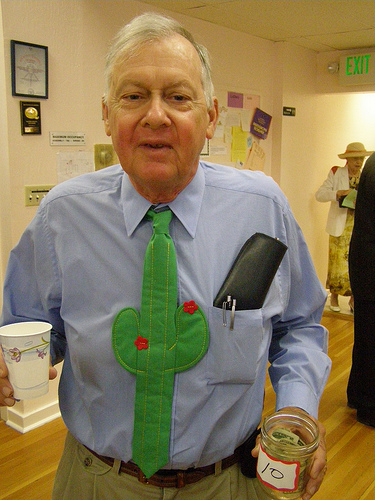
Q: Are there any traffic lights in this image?
A: No, there are no traffic lights.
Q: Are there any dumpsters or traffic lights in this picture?
A: No, there are no traffic lights or dumpsters.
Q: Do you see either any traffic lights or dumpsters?
A: No, there are no traffic lights or dumpsters.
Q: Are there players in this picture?
A: No, there are no players.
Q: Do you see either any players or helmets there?
A: No, there are no players or helmets.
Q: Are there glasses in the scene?
A: No, there are no glasses.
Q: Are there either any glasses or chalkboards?
A: No, there are no glasses or chalkboards.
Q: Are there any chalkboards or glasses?
A: No, there are no glasses or chalkboards.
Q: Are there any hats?
A: Yes, there is a hat.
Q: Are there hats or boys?
A: Yes, there is a hat.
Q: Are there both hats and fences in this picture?
A: No, there is a hat but no fences.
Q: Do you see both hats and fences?
A: No, there is a hat but no fences.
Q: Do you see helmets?
A: No, there are no helmets.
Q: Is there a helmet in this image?
A: No, there are no helmets.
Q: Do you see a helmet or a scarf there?
A: No, there are no helmets or scarves.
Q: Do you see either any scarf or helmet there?
A: No, there are no helmets or scarves.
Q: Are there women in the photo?
A: Yes, there is a woman.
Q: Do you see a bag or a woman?
A: Yes, there is a woman.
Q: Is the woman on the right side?
A: Yes, the woman is on the right of the image.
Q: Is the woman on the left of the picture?
A: No, the woman is on the right of the image.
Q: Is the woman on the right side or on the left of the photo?
A: The woman is on the right of the image.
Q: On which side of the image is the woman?
A: The woman is on the right of the image.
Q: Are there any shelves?
A: No, there are no shelves.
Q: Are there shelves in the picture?
A: No, there are no shelves.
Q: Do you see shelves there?
A: No, there are no shelves.